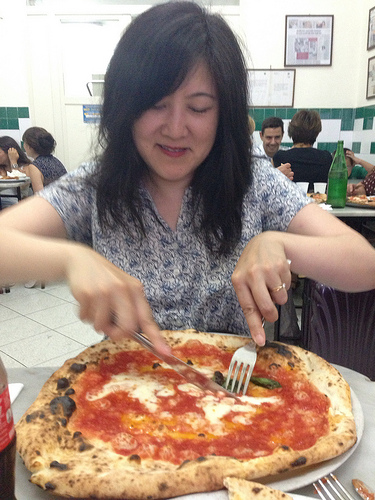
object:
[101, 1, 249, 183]
head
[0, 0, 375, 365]
woman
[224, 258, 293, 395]
fork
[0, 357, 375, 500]
table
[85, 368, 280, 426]
cheese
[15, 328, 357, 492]
pizza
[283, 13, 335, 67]
picture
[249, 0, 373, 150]
wall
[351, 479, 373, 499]
knife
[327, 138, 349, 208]
glass